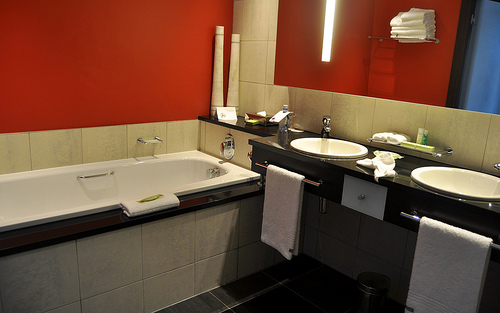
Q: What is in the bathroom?
A: Wash bowls.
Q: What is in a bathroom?
A: A tub.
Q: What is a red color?
A: The wall.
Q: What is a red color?
A: Wall.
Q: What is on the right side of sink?
A: A towel.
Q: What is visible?
A: Bathroom area.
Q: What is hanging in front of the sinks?
A: Towels.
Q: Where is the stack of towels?
A: On a shelf on the wall.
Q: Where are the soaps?
A: On a soap dish.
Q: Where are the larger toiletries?
A: In the corner.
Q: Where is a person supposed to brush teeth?
A: At one of the sinks.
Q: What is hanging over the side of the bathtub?
A: Towel.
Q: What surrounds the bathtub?
A: Tile.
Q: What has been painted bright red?
A: The bathroom walls.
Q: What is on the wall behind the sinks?
A: The mirror.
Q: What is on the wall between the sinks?
A: Small washcloths and small toiletries.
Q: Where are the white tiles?
A: The walls.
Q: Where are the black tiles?
A: The floor.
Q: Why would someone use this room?
A: To take a bath.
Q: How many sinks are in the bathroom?
A: Two.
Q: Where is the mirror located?
A: Above the sinks.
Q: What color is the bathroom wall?
A: Red.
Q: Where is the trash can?
A: Underneath the sinks.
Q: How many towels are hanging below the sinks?
A: Two.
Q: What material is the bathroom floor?
A: Tile.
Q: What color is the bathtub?
A: White.